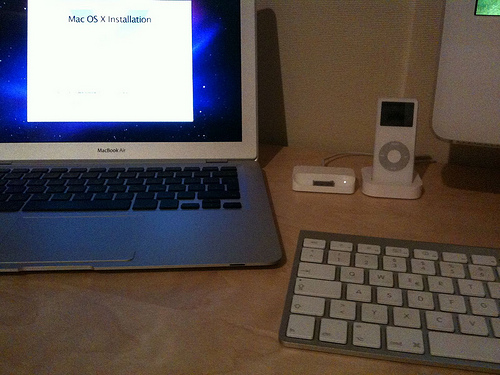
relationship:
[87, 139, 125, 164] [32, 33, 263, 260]
logo on laptop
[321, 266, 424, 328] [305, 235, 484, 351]
key on keyboard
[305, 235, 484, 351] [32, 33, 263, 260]
keyboard on laptop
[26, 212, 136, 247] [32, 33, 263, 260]
mousepad on laptop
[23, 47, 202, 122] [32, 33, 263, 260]
screen on laptop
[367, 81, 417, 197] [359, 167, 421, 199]
ipod on stand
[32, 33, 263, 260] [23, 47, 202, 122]
laptop has screen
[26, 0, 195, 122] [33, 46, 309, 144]
image on screen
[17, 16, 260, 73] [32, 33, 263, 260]
image on laptop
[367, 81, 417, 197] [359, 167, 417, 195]
ipod on stand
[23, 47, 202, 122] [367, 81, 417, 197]
screen on ipod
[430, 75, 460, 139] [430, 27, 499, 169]
corner of monitor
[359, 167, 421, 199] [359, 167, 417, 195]
stand on stand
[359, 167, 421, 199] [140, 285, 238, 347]
stand on desk